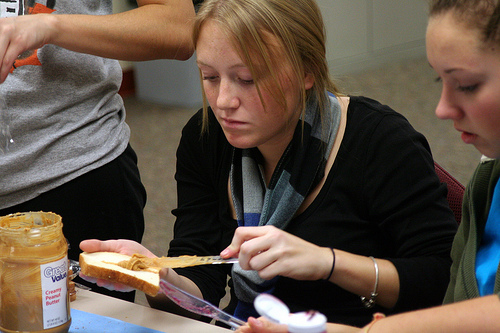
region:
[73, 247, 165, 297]
bread with peanut butter on it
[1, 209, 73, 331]
open jar of peanut butter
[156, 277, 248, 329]
knife with jelly on it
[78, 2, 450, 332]
girl making peanut butter sandwich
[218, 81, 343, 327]
girl wearing gray and black scarf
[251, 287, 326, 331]
jelly with lid open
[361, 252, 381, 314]
silver bracelet on girls arm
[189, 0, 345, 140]
girl has blond hair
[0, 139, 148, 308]
girl with black pants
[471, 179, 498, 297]
girl wearing blue shirt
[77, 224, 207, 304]
spreading peanut butter on bread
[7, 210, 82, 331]
peanut butter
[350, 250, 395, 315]
silver bracelet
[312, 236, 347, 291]
black bracelet on arm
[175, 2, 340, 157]
sandy blonde hair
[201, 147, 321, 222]
grey black and blue scarf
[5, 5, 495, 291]
Three people making a sandwich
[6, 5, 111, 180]
grey t shirt with orange graphix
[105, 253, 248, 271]
knife with peanut butter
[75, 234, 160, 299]
woman holding piece of bread in her right hand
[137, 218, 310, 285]
woman holding knife with her left hand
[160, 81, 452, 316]
woman wearing black top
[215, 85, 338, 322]
scarf tied around woman's neck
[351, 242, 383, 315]
woman wearing silver colored bracelet on her left arm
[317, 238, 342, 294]
woman wearing dark band around her left wrist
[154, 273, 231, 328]
knife with dark pink substance on it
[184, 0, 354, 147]
woman has dark blonde hair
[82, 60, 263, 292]
woman's gaze directed towards bread slice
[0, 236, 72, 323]
container of peanut butter on the table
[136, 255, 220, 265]
a knife with peanut butter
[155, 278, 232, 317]
another knife with jam on it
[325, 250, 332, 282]
part of a black band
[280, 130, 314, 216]
part of a multicoloured showl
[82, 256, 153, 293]
a slice of white bread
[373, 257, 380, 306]
a shiny wristband in the left arm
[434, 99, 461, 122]
a sharp nose of a lady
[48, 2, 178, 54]
a man's arm beside a lady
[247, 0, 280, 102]
part of blonde hair of a lady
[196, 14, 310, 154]
woman looks down at peanut butter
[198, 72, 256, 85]
woman has fairly long dark blonde eyelashes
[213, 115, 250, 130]
woman's mouth without lipstick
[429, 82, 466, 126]
woman has slightly upturned nose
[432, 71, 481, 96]
woman has long dark eyelashes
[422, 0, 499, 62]
woman has curly dark blonde hair, pulled back & away from face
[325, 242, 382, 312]
woman wears black rubber bracelet & silver hippie bracelet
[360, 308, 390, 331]
woman wears salmon color rope bracelet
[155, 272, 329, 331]
woman holds clear plastic knife with a little jelly on it from squeeze jelly jar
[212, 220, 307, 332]
both women have unpolished fingernails